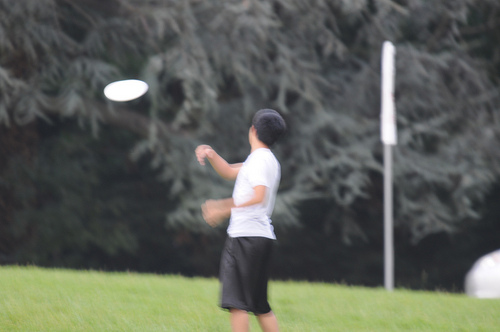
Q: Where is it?
A: This is at the park.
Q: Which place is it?
A: It is a park.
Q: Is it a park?
A: Yes, it is a park.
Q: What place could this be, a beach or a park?
A: It is a park.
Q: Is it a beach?
A: No, it is a park.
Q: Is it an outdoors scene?
A: Yes, it is outdoors.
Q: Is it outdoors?
A: Yes, it is outdoors.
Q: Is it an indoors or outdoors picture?
A: It is outdoors.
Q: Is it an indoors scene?
A: No, it is outdoors.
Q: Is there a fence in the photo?
A: No, there are no fences.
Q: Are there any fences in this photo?
A: No, there are no fences.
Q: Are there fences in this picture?
A: No, there are no fences.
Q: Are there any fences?
A: No, there are no fences.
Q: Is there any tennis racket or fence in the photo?
A: No, there are no fences or rackets.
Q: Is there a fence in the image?
A: No, there are no fences.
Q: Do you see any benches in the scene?
A: No, there are no benches.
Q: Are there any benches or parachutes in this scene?
A: No, there are no benches or parachutes.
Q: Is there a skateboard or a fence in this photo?
A: No, there are no fences or skateboards.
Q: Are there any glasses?
A: No, there are no glasses.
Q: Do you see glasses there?
A: No, there are no glasses.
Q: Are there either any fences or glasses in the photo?
A: No, there are no glasses or fences.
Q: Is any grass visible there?
A: Yes, there is grass.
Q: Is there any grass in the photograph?
A: Yes, there is grass.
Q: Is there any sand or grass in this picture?
A: Yes, there is grass.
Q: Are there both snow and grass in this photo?
A: No, there is grass but no snow.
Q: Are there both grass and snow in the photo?
A: No, there is grass but no snow.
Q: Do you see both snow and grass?
A: No, there is grass but no snow.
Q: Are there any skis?
A: No, there are no skis.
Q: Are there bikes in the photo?
A: No, there are no bikes.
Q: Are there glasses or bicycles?
A: No, there are no bicycles or glasses.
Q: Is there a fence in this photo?
A: No, there are no fences.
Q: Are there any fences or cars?
A: No, there are no fences or cars.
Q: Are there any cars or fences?
A: No, there are no fences or cars.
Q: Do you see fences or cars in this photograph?
A: No, there are no fences or cars.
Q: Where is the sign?
A: The sign is in the park.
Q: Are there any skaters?
A: No, there are no skaters.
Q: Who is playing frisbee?
A: The boy is playing frisbee.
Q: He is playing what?
A: The boy is playing frisbee.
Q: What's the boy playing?
A: The boy is playing frisbee.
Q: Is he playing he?
A: Yes, the boy is playing frisbee.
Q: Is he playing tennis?
A: No, the boy is playing frisbee.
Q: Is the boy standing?
A: Yes, the boy is standing.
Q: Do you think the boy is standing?
A: Yes, the boy is standing.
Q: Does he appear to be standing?
A: Yes, the boy is standing.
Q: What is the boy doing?
A: The boy is standing.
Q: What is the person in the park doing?
A: The boy is standing.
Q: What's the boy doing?
A: The boy is standing.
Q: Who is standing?
A: The boy is standing.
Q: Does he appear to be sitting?
A: No, the boy is standing.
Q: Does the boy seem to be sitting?
A: No, the boy is standing.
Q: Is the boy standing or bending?
A: The boy is standing.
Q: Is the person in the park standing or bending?
A: The boy is standing.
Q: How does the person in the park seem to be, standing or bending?
A: The boy is standing.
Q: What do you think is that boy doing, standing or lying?
A: The boy is standing.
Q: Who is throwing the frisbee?
A: The boy is throwing the frisbee.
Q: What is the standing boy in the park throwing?
A: The boy is throwing the frisbee.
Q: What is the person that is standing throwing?
A: The boy is throwing the frisbee.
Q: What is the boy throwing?
A: The boy is throwing the frisbee.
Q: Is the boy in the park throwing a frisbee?
A: Yes, the boy is throwing a frisbee.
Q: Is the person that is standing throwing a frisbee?
A: Yes, the boy is throwing a frisbee.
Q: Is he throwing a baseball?
A: No, the boy is throwing a frisbee.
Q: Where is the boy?
A: The boy is in the park.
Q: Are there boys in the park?
A: Yes, there is a boy in the park.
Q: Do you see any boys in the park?
A: Yes, there is a boy in the park.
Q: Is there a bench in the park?
A: No, there is a boy in the park.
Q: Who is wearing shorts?
A: The boy is wearing shorts.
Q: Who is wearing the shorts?
A: The boy is wearing shorts.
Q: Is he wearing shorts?
A: Yes, the boy is wearing shorts.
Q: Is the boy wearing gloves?
A: No, the boy is wearing shorts.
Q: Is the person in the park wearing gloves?
A: No, the boy is wearing shorts.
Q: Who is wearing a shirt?
A: The boy is wearing a shirt.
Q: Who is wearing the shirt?
A: The boy is wearing a shirt.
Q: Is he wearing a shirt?
A: Yes, the boy is wearing a shirt.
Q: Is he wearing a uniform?
A: No, the boy is wearing a shirt.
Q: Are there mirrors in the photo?
A: No, there are no mirrors.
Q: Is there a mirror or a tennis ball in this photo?
A: No, there are no mirrors or tennis balls.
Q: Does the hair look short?
A: Yes, the hair is short.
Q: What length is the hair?
A: The hair is short.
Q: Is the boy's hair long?
A: No, the hair is short.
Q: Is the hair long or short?
A: The hair is short.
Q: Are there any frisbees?
A: Yes, there is a frisbee.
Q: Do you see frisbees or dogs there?
A: Yes, there is a frisbee.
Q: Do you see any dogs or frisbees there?
A: Yes, there is a frisbee.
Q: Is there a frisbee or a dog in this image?
A: Yes, there is a frisbee.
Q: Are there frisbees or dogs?
A: Yes, there is a frisbee.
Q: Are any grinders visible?
A: No, there are no grinders.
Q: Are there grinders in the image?
A: No, there are no grinders.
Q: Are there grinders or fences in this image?
A: No, there are no grinders or fences.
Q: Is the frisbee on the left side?
A: Yes, the frisbee is on the left of the image.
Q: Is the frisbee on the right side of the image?
A: No, the frisbee is on the left of the image.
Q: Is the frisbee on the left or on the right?
A: The frisbee is on the left of the image.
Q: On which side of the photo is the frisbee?
A: The frisbee is on the left of the image.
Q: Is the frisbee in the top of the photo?
A: Yes, the frisbee is in the top of the image.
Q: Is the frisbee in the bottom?
A: No, the frisbee is in the top of the image.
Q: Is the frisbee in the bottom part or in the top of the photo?
A: The frisbee is in the top of the image.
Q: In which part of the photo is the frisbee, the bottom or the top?
A: The frisbee is in the top of the image.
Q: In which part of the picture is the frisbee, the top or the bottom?
A: The frisbee is in the top of the image.